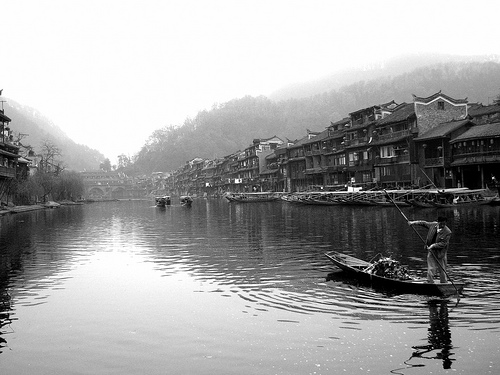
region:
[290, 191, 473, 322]
Man on boat with pole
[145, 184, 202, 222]
three boats coming toward man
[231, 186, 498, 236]
Lots of boats along bank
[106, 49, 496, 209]
Trees behind buildings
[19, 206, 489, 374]
Light reflected on water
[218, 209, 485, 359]
lots of ripples in water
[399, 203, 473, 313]
The man wears jacket and pants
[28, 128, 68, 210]
A tree with no leaves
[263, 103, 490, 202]
The buildings are attached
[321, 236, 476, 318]
mound on boat with man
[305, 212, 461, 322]
a person standing on a boat.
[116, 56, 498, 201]
a forest on a hillside.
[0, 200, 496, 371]
a large body of water.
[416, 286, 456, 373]
a reflection of a human.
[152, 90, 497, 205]
building along a river.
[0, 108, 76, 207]
a lot of trees near a river.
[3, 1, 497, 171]
a hazy sky.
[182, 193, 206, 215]
a boat out on a river.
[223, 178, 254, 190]
lights near a building.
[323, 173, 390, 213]
an object near a river.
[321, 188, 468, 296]
A man on a rowboat.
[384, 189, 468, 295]
A man holds a paddle.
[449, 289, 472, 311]
A paddle in the water.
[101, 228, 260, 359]
The water is still.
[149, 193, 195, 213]
Three boats on the water.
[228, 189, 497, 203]
A group of parked boats.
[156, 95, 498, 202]
Buildings on the water front.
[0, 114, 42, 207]
Homes on the water front.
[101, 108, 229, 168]
Trees behind the building.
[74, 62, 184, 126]
The overcast cloudy ski.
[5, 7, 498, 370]
photo color is black and white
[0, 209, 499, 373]
a river passing through a population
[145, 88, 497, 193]
houses on the right side on the river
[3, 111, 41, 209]
houses on the left side of the river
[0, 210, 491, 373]
water in the river looks murky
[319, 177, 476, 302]
man is traveling on a boat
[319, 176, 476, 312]
man use a rowing to advance in the boat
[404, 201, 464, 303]
man wears a suit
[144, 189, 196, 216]
three boats in a murky river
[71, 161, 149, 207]
a bridge over the river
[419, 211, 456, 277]
this is a man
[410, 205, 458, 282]
he is holding a stick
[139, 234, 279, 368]
the water is calm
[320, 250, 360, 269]
this is a boat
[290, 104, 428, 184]
these are houses in a row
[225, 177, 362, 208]
the boats are parked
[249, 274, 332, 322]
these are water waves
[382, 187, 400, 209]
this is a stick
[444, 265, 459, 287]
the stick is long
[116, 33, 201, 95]
the water is white in color